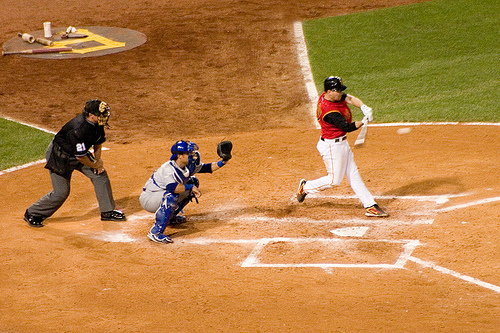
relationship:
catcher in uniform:
[140, 138, 235, 243] [137, 162, 214, 215]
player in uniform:
[293, 74, 389, 218] [303, 94, 376, 209]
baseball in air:
[397, 126, 410, 135] [380, 100, 434, 162]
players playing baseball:
[138, 75, 392, 244] [397, 126, 410, 135]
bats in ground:
[1, 31, 89, 59] [2, 0, 177, 93]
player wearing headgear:
[293, 74, 389, 218] [323, 74, 348, 89]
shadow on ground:
[382, 174, 462, 205] [387, 144, 496, 231]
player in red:
[293, 74, 389, 218] [316, 95, 354, 140]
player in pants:
[293, 74, 389, 218] [305, 137, 378, 206]